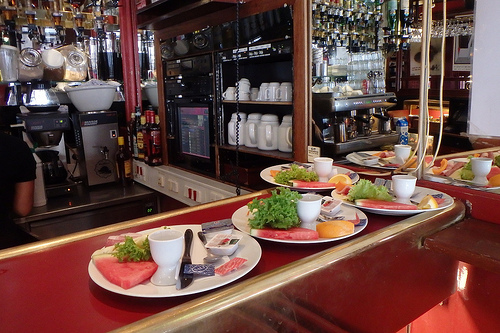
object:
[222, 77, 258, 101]
coffee cups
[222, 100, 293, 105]
shelf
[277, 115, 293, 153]
water jug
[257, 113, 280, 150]
water jug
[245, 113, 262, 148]
water jug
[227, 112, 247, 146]
water jug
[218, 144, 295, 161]
shelf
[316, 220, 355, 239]
orange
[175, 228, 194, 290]
butter knife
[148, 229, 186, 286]
cupe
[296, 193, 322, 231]
cupe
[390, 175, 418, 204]
cupe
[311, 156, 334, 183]
cupe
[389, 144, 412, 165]
cupe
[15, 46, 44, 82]
canister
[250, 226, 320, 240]
watermelon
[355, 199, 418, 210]
watermelon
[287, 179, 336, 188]
watermelon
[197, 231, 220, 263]
spoon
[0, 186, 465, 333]
counter top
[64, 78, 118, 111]
big bowl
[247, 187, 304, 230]
green vegetable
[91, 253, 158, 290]
sliced watermelon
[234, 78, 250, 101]
stack/cups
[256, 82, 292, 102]
coffee cups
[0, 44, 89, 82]
glass canisters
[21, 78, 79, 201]
coffe pot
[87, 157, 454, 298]
four plates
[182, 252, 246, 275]
satchets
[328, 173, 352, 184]
lemon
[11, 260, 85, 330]
red counter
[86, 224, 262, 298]
plate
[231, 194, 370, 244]
plate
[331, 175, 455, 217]
plate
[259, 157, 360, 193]
plate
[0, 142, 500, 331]
table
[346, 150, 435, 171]
plate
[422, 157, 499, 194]
plate